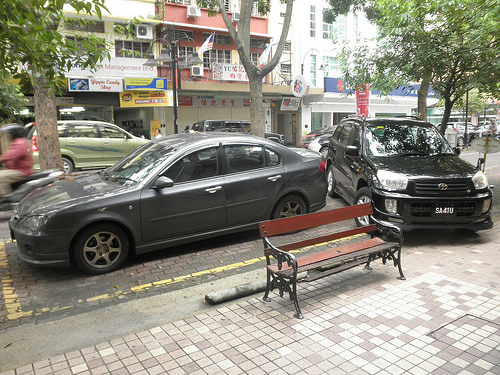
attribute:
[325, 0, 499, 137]
tree — leafy, green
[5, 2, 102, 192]
tree — brown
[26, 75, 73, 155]
trunk — brown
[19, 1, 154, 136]
building — yellow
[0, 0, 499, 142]
building —  white 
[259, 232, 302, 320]
side — mettalic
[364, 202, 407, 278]
side — mettalic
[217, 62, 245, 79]
sign — white, red, chinese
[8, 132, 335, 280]
car — black,  grey , grey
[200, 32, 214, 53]
flag — American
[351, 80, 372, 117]
banner — red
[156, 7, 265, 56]
frame — red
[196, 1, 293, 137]
tree — tall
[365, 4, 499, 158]
tree — tall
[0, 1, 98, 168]
tree — tall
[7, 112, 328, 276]
car — grey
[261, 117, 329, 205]
trunk — tree's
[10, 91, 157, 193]
minivan — silvery and green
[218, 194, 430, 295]
bench — wooden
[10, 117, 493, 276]
cars — black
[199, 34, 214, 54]
flag — red, white, blue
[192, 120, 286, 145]
car — grey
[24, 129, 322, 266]
car — gray, grey, black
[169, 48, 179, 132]
post — black, lamp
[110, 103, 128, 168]
suv — green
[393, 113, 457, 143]
car — gray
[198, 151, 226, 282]
car — grey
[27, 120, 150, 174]
car — light gold